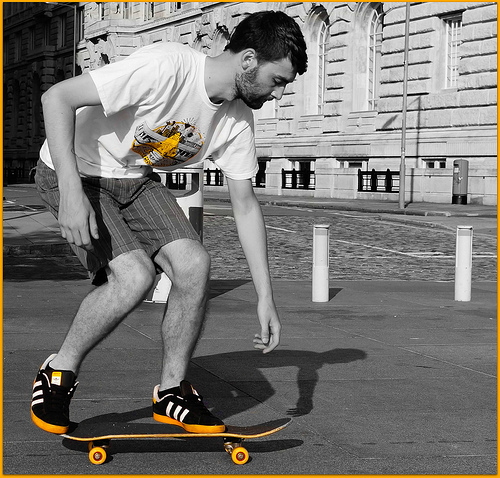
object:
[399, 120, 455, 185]
wall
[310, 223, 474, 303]
posts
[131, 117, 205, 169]
logo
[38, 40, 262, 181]
shirt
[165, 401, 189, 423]
stripes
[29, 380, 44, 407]
stripes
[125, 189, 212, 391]
leg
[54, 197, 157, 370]
leg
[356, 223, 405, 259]
ground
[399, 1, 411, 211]
pole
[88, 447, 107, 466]
yellow wheel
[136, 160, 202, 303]
trash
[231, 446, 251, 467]
wheel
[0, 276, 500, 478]
sidewalk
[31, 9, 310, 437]
guy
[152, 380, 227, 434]
shoe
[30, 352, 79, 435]
shoe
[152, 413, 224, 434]
trim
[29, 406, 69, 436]
trim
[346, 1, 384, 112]
window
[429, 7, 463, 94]
window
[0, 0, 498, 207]
building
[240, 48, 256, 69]
ear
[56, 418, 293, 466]
skateboard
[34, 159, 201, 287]
shorts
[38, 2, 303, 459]
exercise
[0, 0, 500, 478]
day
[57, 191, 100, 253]
hand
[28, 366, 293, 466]
accent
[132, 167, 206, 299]
recepticle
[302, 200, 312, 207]
traffic